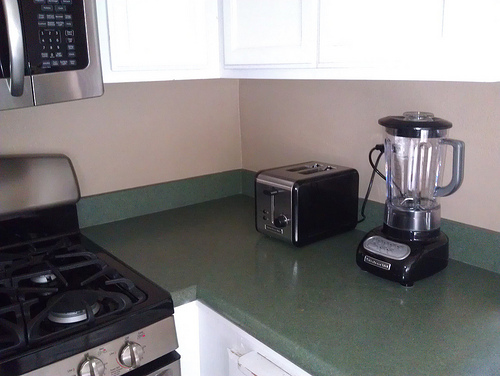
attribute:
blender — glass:
[370, 138, 465, 233]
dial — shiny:
[112, 337, 145, 371]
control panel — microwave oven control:
[31, 0, 86, 77]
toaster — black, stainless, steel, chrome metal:
[250, 160, 361, 250]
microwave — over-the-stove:
[1, 0, 103, 119]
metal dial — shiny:
[118, 340, 150, 371]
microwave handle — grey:
[3, 2, 25, 98]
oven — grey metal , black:
[2, 152, 182, 371]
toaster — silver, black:
[235, 151, 372, 251]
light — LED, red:
[137, 332, 147, 341]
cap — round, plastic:
[374, 106, 459, 136]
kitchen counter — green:
[77, 166, 499, 374]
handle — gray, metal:
[119, 339, 142, 365]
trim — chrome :
[132, 334, 174, 373]